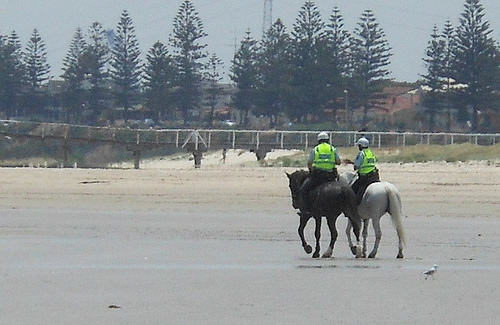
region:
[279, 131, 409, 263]
two people riding horses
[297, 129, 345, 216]
man wearing a reflective vest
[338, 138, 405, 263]
person riding a white horse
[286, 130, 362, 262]
person riding on a black horse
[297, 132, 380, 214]
two people wearing white helmets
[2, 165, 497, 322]
large sandy beach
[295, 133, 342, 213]
man wearing black pants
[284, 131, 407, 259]
two people riding on horses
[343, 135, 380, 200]
person wearing a reflective vest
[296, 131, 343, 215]
person wearing a riding helmet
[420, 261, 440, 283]
small white bird on the ground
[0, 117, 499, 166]
small bridge with white metal fence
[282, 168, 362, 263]
black horse walking in the sand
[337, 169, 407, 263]
white horse walking on the sand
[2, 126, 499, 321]
two people riding on a sandy beach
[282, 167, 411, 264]
two horses carrying people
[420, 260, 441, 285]
white bird walking in the sand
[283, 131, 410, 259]
Police officers riding on horses.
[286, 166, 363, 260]
A trotting black horse.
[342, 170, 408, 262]
A trotting white horse.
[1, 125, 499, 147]
There is a white fence.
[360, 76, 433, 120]
A red building with a black window.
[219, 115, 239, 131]
A small silver car.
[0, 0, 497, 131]
There are many tall trees.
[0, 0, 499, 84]
A gray overcast sky.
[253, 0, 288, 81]
A tall tower behind the trees.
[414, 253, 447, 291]
A bird on a sandy beach.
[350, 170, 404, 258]
The white horse walking on the beach.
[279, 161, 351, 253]
The black horse walking on the beach.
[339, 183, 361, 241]
The tail of the black horse.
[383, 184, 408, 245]
The tail of the white horse.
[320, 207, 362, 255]
The back legs of the black horse.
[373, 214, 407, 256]
The back legs of the white horse.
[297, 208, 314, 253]
The front leg of the black horse.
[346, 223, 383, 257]
The front legs of the white horse.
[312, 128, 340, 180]
The person riding the black horse.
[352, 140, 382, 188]
The person riding the white horse.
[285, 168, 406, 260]
brown and white horses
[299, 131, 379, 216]
two people in green vests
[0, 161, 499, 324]
wide area full of sand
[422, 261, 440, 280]
white bird walking in sand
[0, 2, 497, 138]
line of trees along the beach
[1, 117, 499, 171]
long boardwalk with railing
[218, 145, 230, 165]
woman walking in sand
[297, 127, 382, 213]
two people in white helmets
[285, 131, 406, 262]
workers riding on horses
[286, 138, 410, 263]
Two people on horseback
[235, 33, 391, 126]
Several trees in the distance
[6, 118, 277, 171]
Moderate size bridge over water